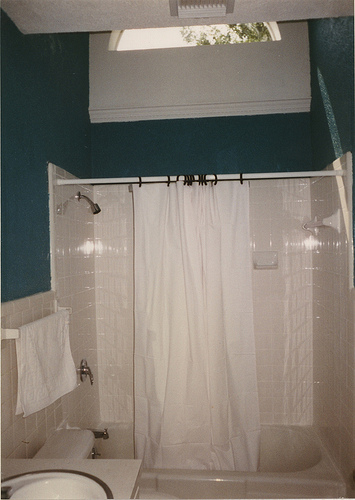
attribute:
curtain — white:
[128, 171, 256, 472]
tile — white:
[283, 184, 312, 421]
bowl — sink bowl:
[10, 454, 97, 496]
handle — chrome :
[72, 357, 100, 386]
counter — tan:
[3, 448, 151, 499]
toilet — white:
[31, 426, 184, 498]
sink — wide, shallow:
[1, 466, 124, 494]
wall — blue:
[6, 146, 31, 271]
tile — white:
[48, 151, 354, 479]